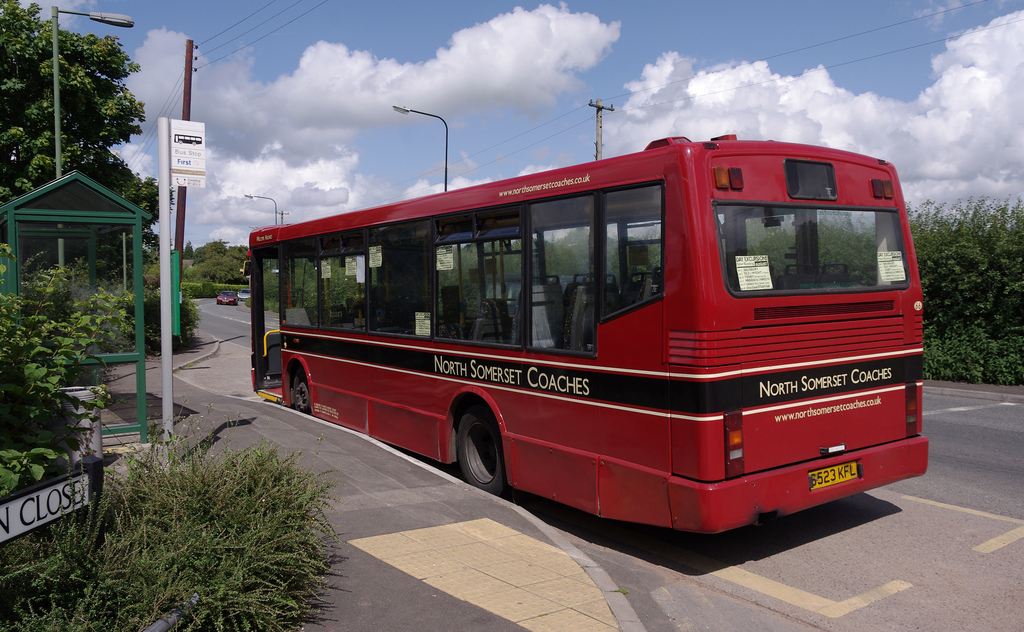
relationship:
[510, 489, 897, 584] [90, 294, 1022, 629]
bus shadow on pavement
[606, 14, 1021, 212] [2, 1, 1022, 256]
cloud in sky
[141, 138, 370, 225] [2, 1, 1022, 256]
cloud in sky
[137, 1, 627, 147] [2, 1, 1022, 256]
cloud in sky